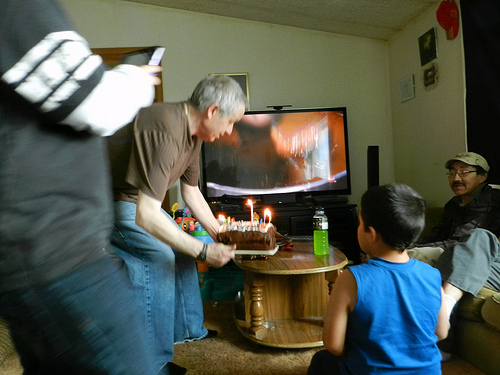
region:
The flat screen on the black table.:
[197, 108, 350, 204]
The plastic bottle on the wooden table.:
[313, 207, 328, 254]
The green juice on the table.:
[313, 230, 328, 253]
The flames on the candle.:
[219, 195, 271, 223]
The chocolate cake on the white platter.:
[219, 216, 274, 249]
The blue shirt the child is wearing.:
[345, 253, 442, 374]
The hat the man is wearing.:
[442, 148, 489, 169]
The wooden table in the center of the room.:
[226, 224, 343, 351]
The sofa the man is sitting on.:
[410, 243, 499, 361]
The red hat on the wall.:
[438, 3, 461, 38]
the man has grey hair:
[191, 71, 245, 117]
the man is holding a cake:
[201, 199, 280, 268]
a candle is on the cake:
[244, 200, 256, 219]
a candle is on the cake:
[216, 212, 226, 223]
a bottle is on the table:
[311, 205, 332, 255]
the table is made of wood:
[208, 231, 343, 353]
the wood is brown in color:
[213, 230, 347, 350]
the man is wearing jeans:
[112, 198, 209, 351]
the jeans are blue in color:
[110, 198, 212, 357]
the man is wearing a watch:
[195, 241, 210, 261]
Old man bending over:
[111, 76, 245, 374]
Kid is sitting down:
[308, 184, 445, 371]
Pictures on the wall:
[397, 25, 438, 101]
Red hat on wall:
[437, 0, 459, 41]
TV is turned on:
[202, 106, 351, 206]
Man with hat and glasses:
[424, 153, 498, 245]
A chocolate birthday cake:
[218, 198, 276, 254]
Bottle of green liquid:
[312, 206, 328, 254]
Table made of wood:
[234, 240, 346, 348]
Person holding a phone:
[5, 0, 165, 373]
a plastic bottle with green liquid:
[312, 206, 329, 258]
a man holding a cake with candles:
[115, 70, 285, 373]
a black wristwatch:
[190, 243, 210, 263]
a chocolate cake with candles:
[212, 199, 277, 253]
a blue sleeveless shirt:
[347, 258, 442, 374]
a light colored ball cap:
[442, 153, 489, 173]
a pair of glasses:
[444, 165, 481, 179]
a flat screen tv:
[200, 105, 350, 205]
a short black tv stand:
[208, 203, 363, 271]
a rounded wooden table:
[230, 235, 350, 352]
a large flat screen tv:
[200, 105, 352, 209]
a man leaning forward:
[111, 72, 279, 342]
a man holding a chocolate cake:
[112, 70, 282, 372]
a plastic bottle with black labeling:
[312, 206, 332, 252]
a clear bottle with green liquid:
[312, 204, 332, 257]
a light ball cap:
[441, 152, 489, 172]